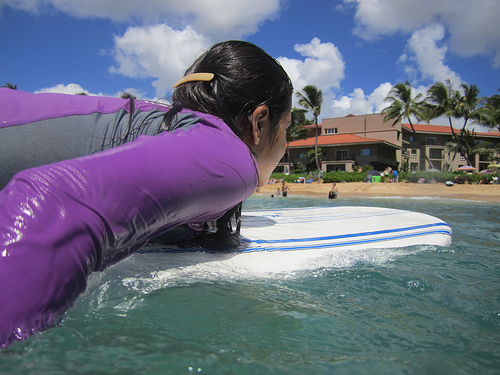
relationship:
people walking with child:
[280, 180, 292, 197] [274, 183, 281, 202]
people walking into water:
[280, 180, 292, 197] [383, 284, 453, 350]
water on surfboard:
[1, 194, 493, 372] [266, 210, 463, 262]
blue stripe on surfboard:
[244, 218, 452, 230] [43, 201, 453, 288]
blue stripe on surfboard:
[224, 230, 454, 257] [43, 201, 453, 288]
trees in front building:
[377, 74, 499, 171] [270, 113, 497, 207]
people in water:
[270, 174, 342, 198] [1, 194, 493, 372]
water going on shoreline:
[1, 194, 493, 372] [337, 190, 497, 203]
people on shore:
[389, 167, 398, 180] [247, 172, 494, 229]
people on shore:
[378, 164, 391, 181] [247, 172, 494, 229]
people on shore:
[294, 175, 304, 182] [247, 172, 494, 229]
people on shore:
[459, 175, 469, 184] [247, 172, 494, 229]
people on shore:
[476, 173, 491, 183] [247, 172, 494, 229]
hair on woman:
[146, 36, 298, 253] [0, 39, 293, 349]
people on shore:
[274, 174, 362, 206] [358, 189, 472, 208]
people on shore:
[326, 182, 339, 199] [258, 176, 496, 215]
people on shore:
[280, 180, 292, 197] [258, 176, 496, 215]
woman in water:
[18, 38, 302, 348] [1, 194, 493, 372]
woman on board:
[18, 38, 302, 348] [86, 202, 453, 291]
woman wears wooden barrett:
[18, 38, 302, 348] [172, 71, 218, 92]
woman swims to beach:
[18, 38, 302, 348] [264, 147, 499, 231]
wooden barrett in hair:
[172, 71, 218, 92] [146, 36, 298, 253]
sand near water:
[254, 179, 498, 200] [1, 194, 493, 372]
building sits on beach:
[262, 109, 497, 185] [261, 180, 485, 205]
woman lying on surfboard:
[18, 38, 302, 348] [106, 200, 454, 281]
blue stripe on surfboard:
[224, 230, 452, 252] [104, 204, 455, 285]